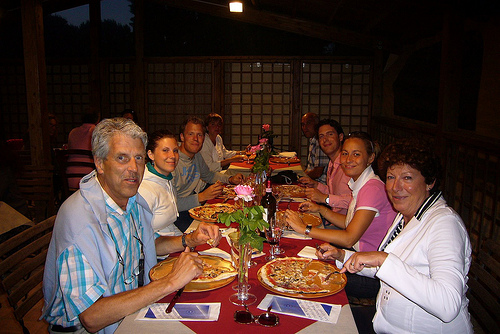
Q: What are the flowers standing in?
A: A vase.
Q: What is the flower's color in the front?
A: Pink.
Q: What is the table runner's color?
A: Red.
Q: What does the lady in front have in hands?
A: A fork and a knife.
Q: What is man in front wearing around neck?
A: A sweater.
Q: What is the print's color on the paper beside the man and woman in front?
A: Blue.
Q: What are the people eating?
A: A pizza.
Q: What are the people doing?
A: Looking at the camera.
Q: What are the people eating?
A: Pizza.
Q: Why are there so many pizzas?
A: They are personal pizzas.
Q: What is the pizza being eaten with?
A: Forks and knives.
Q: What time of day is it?
A: Dusk.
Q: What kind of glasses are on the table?
A: Sunglasses.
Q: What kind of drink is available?
A: Wine.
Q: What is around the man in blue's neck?
A: Glasses.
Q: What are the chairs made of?
A: Wood.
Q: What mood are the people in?
A: Happy.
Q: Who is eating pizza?
A: The people.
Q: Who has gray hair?
A: The man.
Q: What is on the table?
A: White and red cloth.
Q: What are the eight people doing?
A: Eating.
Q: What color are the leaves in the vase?
A: Green.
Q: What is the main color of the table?
A: Red.